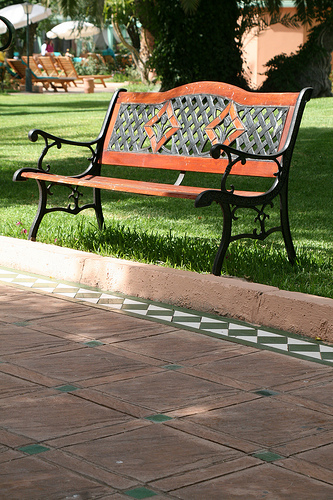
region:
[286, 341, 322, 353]
green colored diamond tile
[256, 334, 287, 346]
green colored diamond tile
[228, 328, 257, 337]
green colored diamond tile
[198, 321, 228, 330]
green colored diamond tile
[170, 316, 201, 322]
green colored diamond tile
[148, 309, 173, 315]
green colored diamond tile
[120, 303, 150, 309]
green colored diamond tile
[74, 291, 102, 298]
green colored diamond tile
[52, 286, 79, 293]
green colored diamond tile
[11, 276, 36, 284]
green colored diamond tile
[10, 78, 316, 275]
a bench in the park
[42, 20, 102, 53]
umbrella structure over seating area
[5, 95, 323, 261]
green space in the park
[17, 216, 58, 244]
flowers in the park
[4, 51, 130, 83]
wooden chairs in seating area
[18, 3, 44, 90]
light in the park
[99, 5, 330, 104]
tree behind the bench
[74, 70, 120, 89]
concrete area in seating area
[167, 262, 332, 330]
concrete curb by bench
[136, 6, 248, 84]
green plant on the tree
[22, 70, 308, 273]
bench in the grass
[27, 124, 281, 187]
black armrests on the bench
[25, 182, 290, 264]
black legs of the bench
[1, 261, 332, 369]
green and white border on the sidewalk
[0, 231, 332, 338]
curb of the sidewalk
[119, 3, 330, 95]
tree covered in ivy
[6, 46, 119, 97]
four chairs in the background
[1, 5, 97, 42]
two white umbrellas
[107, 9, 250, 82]
ivy covered tree behind bench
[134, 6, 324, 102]
peach colored building behind tree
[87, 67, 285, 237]
the bench is made of wood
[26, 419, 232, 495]
the ground has green squares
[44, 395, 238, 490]
the ground is made of squares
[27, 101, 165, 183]
the bench is wood and black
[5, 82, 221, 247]
the sun is shining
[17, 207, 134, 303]
the sun is on the curb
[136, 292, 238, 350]
tile is by the curb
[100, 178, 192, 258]
grass is underneath the bench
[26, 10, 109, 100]
sun is on the chairs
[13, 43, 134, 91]
beach chairs are by the pool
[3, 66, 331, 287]
a park bench on the grass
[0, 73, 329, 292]
the bench is made of wood and iron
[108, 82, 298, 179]
the back rest has a beautiful design and patter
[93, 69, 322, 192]
the backrest features an elaborate design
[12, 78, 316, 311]
the legs of the bench and the middle of the backrest are made of iron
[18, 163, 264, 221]
the seat of the bench is made of wood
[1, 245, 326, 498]
the walkway features a tiled pattern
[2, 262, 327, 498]
the walkway features white and green tiles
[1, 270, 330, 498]
the walkway also features reddish stone squares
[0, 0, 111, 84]
there are wooden lounge chairs and white umbrellas in the background